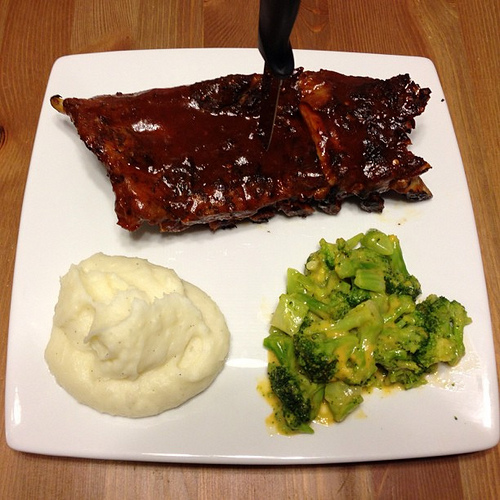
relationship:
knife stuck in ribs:
[259, 0, 302, 152] [50, 65, 432, 234]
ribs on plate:
[50, 65, 432, 234] [5, 46, 499, 468]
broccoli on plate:
[414, 295, 472, 368] [5, 46, 499, 468]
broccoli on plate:
[354, 266, 386, 294] [5, 46, 499, 468]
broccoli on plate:
[269, 294, 310, 338] [5, 46, 499, 468]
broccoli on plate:
[293, 299, 382, 387] [5, 46, 499, 468]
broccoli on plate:
[267, 366, 327, 431] [5, 46, 499, 468]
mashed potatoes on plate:
[44, 252, 231, 420] [5, 46, 499, 468]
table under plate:
[1, 0, 500, 499] [5, 46, 499, 468]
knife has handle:
[259, 0, 302, 152] [258, 0, 301, 76]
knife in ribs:
[259, 0, 302, 152] [50, 65, 432, 234]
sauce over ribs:
[65, 69, 367, 229] [50, 65, 432, 234]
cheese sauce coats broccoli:
[256, 379, 373, 435] [267, 366, 327, 431]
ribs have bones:
[50, 65, 432, 234] [160, 178, 434, 233]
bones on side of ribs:
[160, 178, 434, 233] [50, 65, 432, 234]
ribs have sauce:
[50, 65, 432, 234] [65, 69, 367, 229]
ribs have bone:
[50, 65, 432, 234] [49, 95, 66, 114]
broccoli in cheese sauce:
[267, 366, 327, 431] [256, 379, 373, 435]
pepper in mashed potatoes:
[116, 340, 122, 346] [44, 252, 231, 420]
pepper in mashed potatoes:
[178, 371, 183, 378] [44, 252, 231, 420]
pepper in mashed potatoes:
[135, 261, 142, 267] [44, 252, 231, 420]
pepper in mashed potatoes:
[73, 328, 78, 333] [44, 252, 231, 420]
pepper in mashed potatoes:
[90, 368, 94, 373] [44, 252, 231, 420]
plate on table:
[5, 46, 499, 468] [1, 0, 500, 499]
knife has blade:
[259, 0, 302, 152] [258, 60, 285, 151]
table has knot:
[1, 0, 500, 499] [300, 4, 332, 33]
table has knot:
[1, 0, 500, 499] [110, 36, 143, 51]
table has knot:
[1, 0, 500, 499] [0, 128, 4, 147]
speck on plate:
[441, 97, 446, 102] [5, 46, 499, 468]